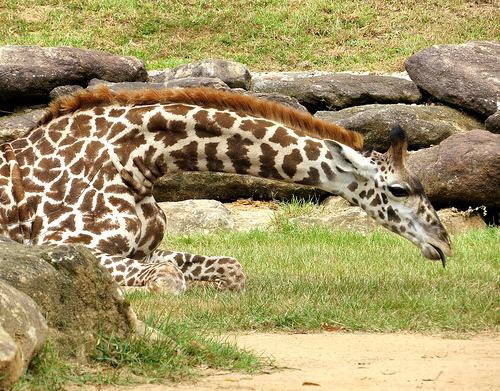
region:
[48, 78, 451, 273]
reclined giraffe bending over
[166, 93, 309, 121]
brown mane on giraffe's neck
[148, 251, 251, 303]
folded knees on giraffe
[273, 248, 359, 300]
grass under giraffe neck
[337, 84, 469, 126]
rock pile behind giraffe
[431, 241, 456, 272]
tongue sticking out of mouth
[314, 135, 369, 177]
white ear on giraffe head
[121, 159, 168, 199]
wrinkled bottom of giraffe neck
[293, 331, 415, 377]
dirt in front of grass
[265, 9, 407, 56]
grass behind dirt pile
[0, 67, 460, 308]
brown and white giraffe arching neck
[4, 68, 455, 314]
giraffe sitting near rocks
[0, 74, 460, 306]
giraffe kneeling on grass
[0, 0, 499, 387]
short green grass patches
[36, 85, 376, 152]
long brown mane on giraffe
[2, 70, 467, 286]
giraffe sitting with tongue out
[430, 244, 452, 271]
long gray giraffe rongue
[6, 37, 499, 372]
large grey boulder rocks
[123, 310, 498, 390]
brown path of earth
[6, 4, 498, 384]
this is a sunny outdoor daytime scene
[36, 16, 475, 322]
a large giraffe resting.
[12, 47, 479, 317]
a large giraffe resting between some rocks.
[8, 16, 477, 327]
a large giraffe kneeling down.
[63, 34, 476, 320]
large giraffe leaning close to the ground.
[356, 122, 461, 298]
head of a giraffe.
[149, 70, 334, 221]
neck of a giraffe.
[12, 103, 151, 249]
body of a giraffe.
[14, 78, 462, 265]
a big brown and white giraffe.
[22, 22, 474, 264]
giraffe near a cluster of rocks.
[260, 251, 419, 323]
a patch of green grass.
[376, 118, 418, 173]
horns on a giraffe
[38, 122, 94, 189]
browns spots on a giraffe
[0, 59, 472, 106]
several large rocks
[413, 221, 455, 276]
a giraffe's tongue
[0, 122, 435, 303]
a giraffe sitting on the ground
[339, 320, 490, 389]
a patch of sand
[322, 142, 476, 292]
a giraffe sticking its tongue out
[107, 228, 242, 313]
a giraffes legs bent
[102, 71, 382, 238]
a giraffe's long neck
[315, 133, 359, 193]
a giraffe's ear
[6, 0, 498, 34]
this is the grass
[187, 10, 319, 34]
the grass is green in color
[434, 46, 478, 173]
these are some rocks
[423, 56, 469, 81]
the rocks are grey in color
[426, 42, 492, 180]
the rocks are big in size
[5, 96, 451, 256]
this is a giraffe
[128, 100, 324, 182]
the giraffe's neck is long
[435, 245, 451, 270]
the giraffe's tongue is out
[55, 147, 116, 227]
the fur is brown in color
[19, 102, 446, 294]
the giraffe is seated